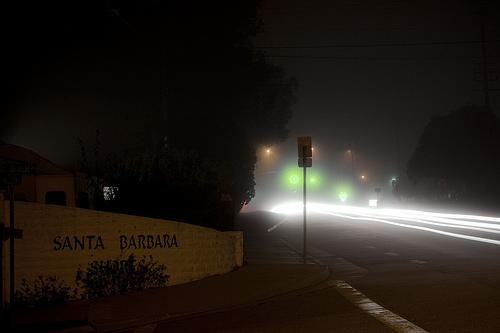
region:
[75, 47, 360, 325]
picture taken outdoors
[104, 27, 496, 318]
picture taken during the evening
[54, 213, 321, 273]
a brick wall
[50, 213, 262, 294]
the words Santa Barbara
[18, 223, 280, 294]
Santa Barbara on the brick wall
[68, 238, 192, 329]
small plants next to the wall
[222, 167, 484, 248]
lights are green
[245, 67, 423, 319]
it is a foggy night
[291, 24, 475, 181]
the sky is dark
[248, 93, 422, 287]
the lights are faded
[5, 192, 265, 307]
white sign on the curb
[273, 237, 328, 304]
street curb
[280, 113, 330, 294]
tall sign on the curb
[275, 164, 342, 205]
green lights lighting up the street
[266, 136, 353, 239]
fog by the lights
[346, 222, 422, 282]
white dashes on the road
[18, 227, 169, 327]
bushes in front of the sign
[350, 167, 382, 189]
a yellow light in the sky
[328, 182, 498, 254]
white streaks of light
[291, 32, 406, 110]
dark foggy sky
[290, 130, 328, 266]
This is a sign post.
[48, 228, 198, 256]
The name on the wall is Santa Barbara.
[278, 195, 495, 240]
This is a car light.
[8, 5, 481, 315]
The time of day is night time.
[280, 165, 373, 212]
The lights are green.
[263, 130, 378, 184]
The street lights are orange in color.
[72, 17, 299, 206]
This is a big tree.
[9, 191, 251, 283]
This wall is white.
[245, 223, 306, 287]
This is a sidewalk.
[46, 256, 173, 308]
There are bushes in front of the wall.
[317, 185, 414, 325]
the road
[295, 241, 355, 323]
the road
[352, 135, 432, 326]
the road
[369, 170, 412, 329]
the road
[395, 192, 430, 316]
the road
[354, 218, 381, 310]
the road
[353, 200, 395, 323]
the road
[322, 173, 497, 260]
Car lights zooming by.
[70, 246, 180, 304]
A little bush growing near the wall.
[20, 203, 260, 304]
A wall with white bricks.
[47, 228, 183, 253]
The black text on the wall says Santa Barbara.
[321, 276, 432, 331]
A white line painted on the street.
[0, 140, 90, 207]
A house behind the brick wall.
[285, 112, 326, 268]
The back of a street sign.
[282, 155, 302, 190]
A green street light in the distance.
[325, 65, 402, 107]
The sky is dark.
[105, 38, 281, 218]
Trees near the wall.